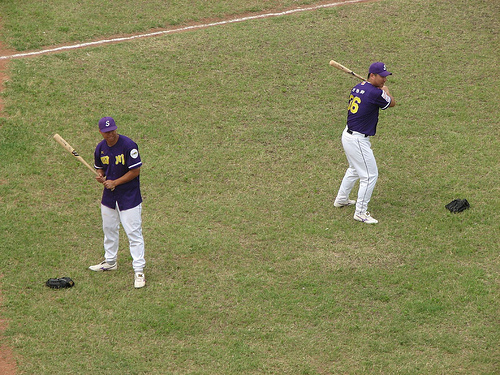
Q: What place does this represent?
A: It represents the field.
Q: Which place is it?
A: It is a field.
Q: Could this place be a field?
A: Yes, it is a field.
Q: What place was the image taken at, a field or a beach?
A: It was taken at a field.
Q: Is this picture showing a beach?
A: No, the picture is showing a field.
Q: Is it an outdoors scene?
A: Yes, it is outdoors.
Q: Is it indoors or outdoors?
A: It is outdoors.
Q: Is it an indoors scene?
A: No, it is outdoors.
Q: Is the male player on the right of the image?
A: Yes, the player is on the right of the image.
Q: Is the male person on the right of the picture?
A: Yes, the player is on the right of the image.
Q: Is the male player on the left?
A: No, the player is on the right of the image.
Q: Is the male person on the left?
A: No, the player is on the right of the image.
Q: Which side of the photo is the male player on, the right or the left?
A: The player is on the right of the image.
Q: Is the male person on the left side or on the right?
A: The player is on the right of the image.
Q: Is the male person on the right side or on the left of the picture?
A: The player is on the right of the image.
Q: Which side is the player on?
A: The player is on the right of the image.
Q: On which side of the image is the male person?
A: The player is on the right of the image.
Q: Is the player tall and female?
A: No, the player is tall but male.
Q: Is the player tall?
A: Yes, the player is tall.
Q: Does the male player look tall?
A: Yes, the player is tall.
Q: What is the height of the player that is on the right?
A: The player is tall.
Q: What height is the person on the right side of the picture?
A: The player is tall.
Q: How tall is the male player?
A: The player is tall.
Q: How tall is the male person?
A: The player is tall.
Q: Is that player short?
A: No, the player is tall.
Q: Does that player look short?
A: No, the player is tall.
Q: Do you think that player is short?
A: No, the player is tall.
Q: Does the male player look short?
A: No, the player is tall.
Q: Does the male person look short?
A: No, the player is tall.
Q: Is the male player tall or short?
A: The player is tall.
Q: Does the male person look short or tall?
A: The player is tall.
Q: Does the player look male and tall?
A: Yes, the player is male and tall.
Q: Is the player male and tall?
A: Yes, the player is male and tall.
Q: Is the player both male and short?
A: No, the player is male but tall.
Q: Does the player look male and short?
A: No, the player is male but tall.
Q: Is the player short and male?
A: No, the player is male but tall.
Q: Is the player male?
A: Yes, the player is male.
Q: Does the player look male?
A: Yes, the player is male.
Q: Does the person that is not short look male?
A: Yes, the player is male.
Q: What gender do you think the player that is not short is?
A: The player is male.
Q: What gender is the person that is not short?
A: The player is male.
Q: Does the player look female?
A: No, the player is male.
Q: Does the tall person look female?
A: No, the player is male.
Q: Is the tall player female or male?
A: The player is male.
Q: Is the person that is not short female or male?
A: The player is male.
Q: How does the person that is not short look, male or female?
A: The player is male.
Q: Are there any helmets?
A: No, there are no helmets.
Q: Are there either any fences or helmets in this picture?
A: No, there are no helmets or fences.